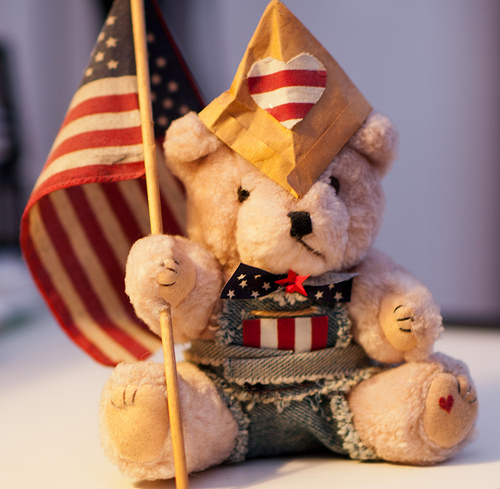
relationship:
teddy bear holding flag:
[98, 3, 476, 487] [18, 7, 216, 487]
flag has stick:
[18, 7, 216, 487] [129, 0, 191, 489]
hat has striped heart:
[197, 5, 375, 200] [249, 52, 326, 133]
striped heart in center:
[249, 52, 326, 133] [253, 10, 331, 178]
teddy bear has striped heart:
[98, 3, 476, 487] [249, 52, 326, 133]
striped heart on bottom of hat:
[249, 52, 326, 133] [197, 5, 375, 200]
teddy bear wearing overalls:
[98, 3, 476, 487] [188, 254, 378, 463]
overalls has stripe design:
[188, 254, 378, 463] [242, 311, 332, 349]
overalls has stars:
[188, 254, 378, 463] [223, 269, 358, 296]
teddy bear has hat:
[98, 3, 476, 487] [197, 5, 375, 200]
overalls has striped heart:
[188, 254, 378, 463] [242, 311, 332, 349]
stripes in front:
[242, 311, 332, 349] [208, 269, 364, 420]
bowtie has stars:
[224, 267, 352, 311] [223, 269, 358, 296]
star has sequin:
[275, 269, 309, 299] [285, 274, 300, 294]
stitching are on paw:
[114, 390, 140, 416] [104, 356, 221, 488]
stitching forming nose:
[255, 214, 329, 262] [289, 210, 317, 240]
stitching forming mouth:
[255, 214, 329, 262] [269, 228, 328, 268]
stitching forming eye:
[231, 172, 344, 208] [234, 183, 258, 206]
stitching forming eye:
[231, 172, 344, 208] [323, 172, 350, 196]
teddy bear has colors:
[98, 3, 476, 487] [239, 3, 336, 355]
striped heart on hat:
[249, 52, 326, 133] [197, 5, 375, 200]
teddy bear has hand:
[98, 3, 476, 487] [126, 238, 214, 334]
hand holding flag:
[126, 238, 214, 334] [18, 7, 216, 487]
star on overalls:
[275, 269, 309, 299] [188, 254, 378, 463]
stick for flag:
[129, 0, 191, 489] [18, 7, 216, 487]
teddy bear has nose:
[98, 3, 476, 487] [289, 210, 317, 240]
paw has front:
[104, 356, 221, 488] [112, 377, 165, 463]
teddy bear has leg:
[98, 3, 476, 487] [335, 351, 472, 456]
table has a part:
[0, 255, 500, 488] [40, 367, 72, 410]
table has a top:
[0, 255, 500, 488] [10, 265, 499, 485]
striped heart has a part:
[249, 52, 326, 133] [284, 82, 324, 100]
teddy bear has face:
[98, 3, 476, 487] [189, 138, 383, 274]